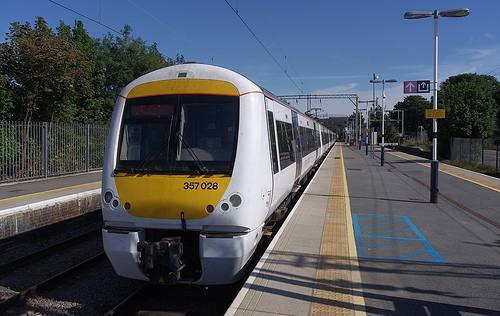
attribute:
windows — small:
[115, 92, 240, 175]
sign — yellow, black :
[395, 75, 436, 96]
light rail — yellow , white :
[98, 60, 340, 290]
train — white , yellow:
[97, 60, 342, 289]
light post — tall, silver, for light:
[392, 9, 476, 215]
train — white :
[230, 68, 329, 195]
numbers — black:
[165, 173, 225, 200]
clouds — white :
[286, 70, 413, 133]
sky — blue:
[249, 0, 365, 67]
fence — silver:
[1, 117, 106, 174]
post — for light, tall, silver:
[420, 45, 457, 209]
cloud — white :
[287, 76, 432, 116]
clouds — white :
[285, 31, 497, 118]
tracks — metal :
[0, 207, 223, 313]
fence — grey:
[5, 115, 115, 179]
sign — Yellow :
[417, 103, 460, 129]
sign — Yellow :
[419, 106, 454, 122]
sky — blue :
[2, 0, 499, 115]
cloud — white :
[279, 72, 369, 79]